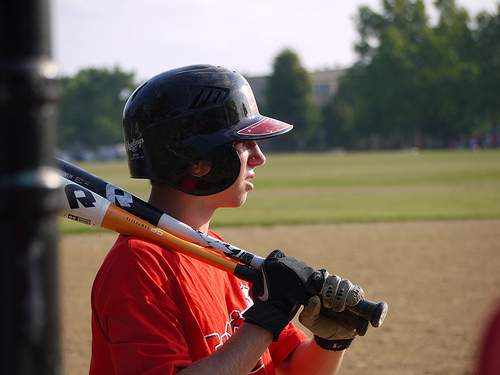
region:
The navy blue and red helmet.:
[122, 63, 296, 196]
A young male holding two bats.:
[58, 68, 386, 373]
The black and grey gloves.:
[236, 250, 365, 351]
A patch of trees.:
[307, 1, 498, 156]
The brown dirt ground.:
[393, 224, 498, 320]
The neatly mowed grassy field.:
[328, 149, 498, 221]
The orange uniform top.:
[92, 235, 309, 373]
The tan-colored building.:
[308, 70, 341, 106]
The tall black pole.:
[1, 0, 65, 373]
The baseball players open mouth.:
[241, 171, 256, 189]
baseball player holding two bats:
[36, 18, 486, 336]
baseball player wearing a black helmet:
[85, 37, 291, 218]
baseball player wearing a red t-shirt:
[94, 219, 308, 370]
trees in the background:
[64, 6, 496, 193]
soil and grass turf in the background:
[65, 132, 498, 264]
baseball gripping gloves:
[241, 246, 408, 373]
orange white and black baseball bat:
[41, 77, 413, 373]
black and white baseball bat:
[34, 99, 413, 336]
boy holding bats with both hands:
[71, 87, 444, 367]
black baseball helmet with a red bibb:
[110, 50, 300, 212]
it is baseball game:
[5, 11, 399, 368]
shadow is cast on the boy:
[157, 134, 200, 206]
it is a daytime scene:
[35, 108, 499, 373]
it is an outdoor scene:
[8, 109, 377, 371]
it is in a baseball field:
[3, 103, 499, 346]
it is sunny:
[10, 35, 421, 334]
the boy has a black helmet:
[88, 88, 311, 171]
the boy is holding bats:
[31, 107, 432, 362]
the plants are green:
[297, 94, 453, 206]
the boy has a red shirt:
[111, 233, 274, 373]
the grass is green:
[359, 175, 449, 211]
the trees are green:
[373, 78, 461, 107]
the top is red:
[134, 262, 198, 342]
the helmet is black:
[145, 87, 259, 123]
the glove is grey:
[324, 274, 367, 359]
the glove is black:
[262, 256, 299, 308]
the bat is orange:
[74, 195, 226, 272]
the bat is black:
[93, 177, 139, 202]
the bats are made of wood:
[96, 196, 228, 263]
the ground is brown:
[413, 238, 450, 287]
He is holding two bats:
[67, 45, 387, 369]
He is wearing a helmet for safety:
[79, 66, 296, 251]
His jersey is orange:
[82, 167, 291, 373]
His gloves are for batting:
[213, 225, 393, 366]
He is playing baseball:
[68, 80, 473, 347]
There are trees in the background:
[126, 60, 493, 198]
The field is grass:
[105, 118, 497, 312]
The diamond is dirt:
[177, 213, 477, 365]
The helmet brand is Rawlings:
[95, 115, 232, 190]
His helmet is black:
[123, 75, 311, 304]